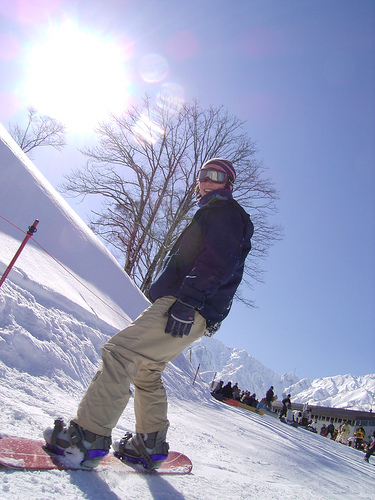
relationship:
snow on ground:
[242, 429, 320, 460] [165, 433, 348, 495]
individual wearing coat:
[43, 157, 254, 471] [148, 191, 253, 337]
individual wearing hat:
[43, 157, 254, 471] [178, 146, 259, 196]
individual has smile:
[43, 157, 254, 471] [200, 188, 217, 199]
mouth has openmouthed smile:
[194, 175, 226, 202] [200, 188, 217, 199]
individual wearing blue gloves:
[43, 157, 254, 471] [164, 298, 196, 338]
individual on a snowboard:
[48, 154, 253, 470] [0, 432, 193, 470]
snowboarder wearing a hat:
[40, 158, 258, 473] [204, 157, 239, 179]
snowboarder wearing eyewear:
[40, 158, 258, 473] [195, 168, 227, 183]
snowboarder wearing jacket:
[0, 161, 256, 475] [146, 202, 255, 329]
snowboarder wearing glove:
[0, 161, 256, 475] [160, 290, 196, 337]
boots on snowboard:
[71, 421, 227, 462] [24, 426, 231, 478]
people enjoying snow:
[211, 367, 368, 457] [3, 143, 373, 494]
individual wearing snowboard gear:
[48, 154, 253, 470] [0, 157, 253, 469]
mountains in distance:
[181, 329, 374, 419] [190, 332, 374, 417]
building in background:
[268, 395, 373, 447] [238, 361, 356, 448]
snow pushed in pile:
[242, 429, 320, 460] [1, 129, 95, 371]